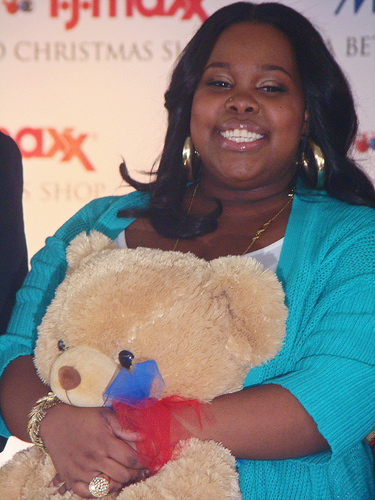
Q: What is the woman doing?
A: Laughing.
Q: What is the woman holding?
A: Bear.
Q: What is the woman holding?
A: Bear.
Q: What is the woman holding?
A: Teddy bear.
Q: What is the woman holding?
A: Doll.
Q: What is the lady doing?
A: Sitting.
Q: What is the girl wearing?
A: Earrings.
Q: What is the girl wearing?
A: Shirt.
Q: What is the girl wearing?
A: Shirt.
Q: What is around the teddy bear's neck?
A: Ribbon.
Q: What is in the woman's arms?
A: Teddy bear.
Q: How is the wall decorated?
A: Writing.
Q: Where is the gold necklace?
A: Woman's neck.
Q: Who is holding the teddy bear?
A: Woman in blue.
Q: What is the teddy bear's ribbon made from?
A: Netting.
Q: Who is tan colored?
A: Teddy bear.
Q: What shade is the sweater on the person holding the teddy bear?
A: Blue.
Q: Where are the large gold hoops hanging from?
A: Ears.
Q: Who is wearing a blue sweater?
A: Woman with teddy bear.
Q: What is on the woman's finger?
A: A ring.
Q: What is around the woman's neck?
A: A necklace.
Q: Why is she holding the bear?
A: Comfort.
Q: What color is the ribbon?
A: Red and blue.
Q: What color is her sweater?
A: Blue.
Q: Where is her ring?
A: Right finger.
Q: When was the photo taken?
A: Daytime.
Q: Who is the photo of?
A: A woman.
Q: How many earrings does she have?
A: Two.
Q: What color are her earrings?
A: Gold.